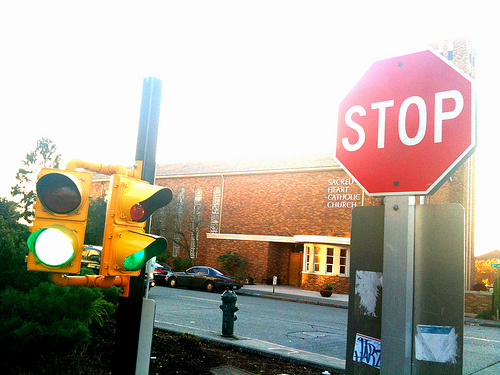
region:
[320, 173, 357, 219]
the name of the building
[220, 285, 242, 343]
green fire hydrant on sidewalk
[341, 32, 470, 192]
a stop sign on street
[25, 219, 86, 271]
the green light on traffic signal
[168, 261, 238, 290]
a car parked on street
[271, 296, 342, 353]
part of the street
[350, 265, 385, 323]
paper stuck on back of sign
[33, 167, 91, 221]
the top light on traffic signal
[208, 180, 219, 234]
stained window in building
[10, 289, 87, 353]
part of a green shrub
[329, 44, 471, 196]
a red and white stop sign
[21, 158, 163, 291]
a yellow traffic light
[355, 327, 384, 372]
a sticker on the back of a sign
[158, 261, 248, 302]
a black car parked on the side of a road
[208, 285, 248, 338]
a green fire hydrant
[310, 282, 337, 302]
a clay flower pot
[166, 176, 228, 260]
three long windows in a building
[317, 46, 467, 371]
a traffic sign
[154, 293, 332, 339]
a paved road way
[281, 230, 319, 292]
doorway of a building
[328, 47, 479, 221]
A stop sign.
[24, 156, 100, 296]
A traffic signal showing green.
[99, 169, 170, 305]
A traffic signal showing green.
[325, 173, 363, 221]
The sign for the church.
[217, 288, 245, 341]
A green fire hydrant.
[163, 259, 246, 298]
A dark colored car.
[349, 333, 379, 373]
A sticker with graffiti on it.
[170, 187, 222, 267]
Several stained glass windows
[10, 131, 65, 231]
A tree.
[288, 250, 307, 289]
The entrance of the church.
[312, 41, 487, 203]
red and white sign o a post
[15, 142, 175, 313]
traffic signal on a pole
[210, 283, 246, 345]
fire hydrant on a sidewalk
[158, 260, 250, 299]
car parked on a street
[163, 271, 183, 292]
front wheel of a vehicle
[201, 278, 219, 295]
rear wheel of a vehicle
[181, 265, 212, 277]
side windows of a vehicle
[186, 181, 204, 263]
window on a building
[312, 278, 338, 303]
potted plant on a sidewalk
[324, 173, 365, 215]
lettering on a building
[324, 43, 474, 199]
A RED STOP SIGN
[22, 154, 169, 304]
TRAFFIC SIGNAL LIGHTS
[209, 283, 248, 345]
A GREEN FIRE HYDRANT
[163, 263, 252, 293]
A CAR PARKED AT THE CURB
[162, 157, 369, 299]
A CATHOLIC CHURCH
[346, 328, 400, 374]
A STICKER ON BACK OF A SIGN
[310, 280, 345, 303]
A PLANTER ON THE SIDEWALK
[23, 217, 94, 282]
A GREEN TRAFFIC LIGHT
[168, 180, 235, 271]
THREE CHURCH WINDOWS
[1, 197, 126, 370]
BUSHES NEAR THE STREET LIGHT